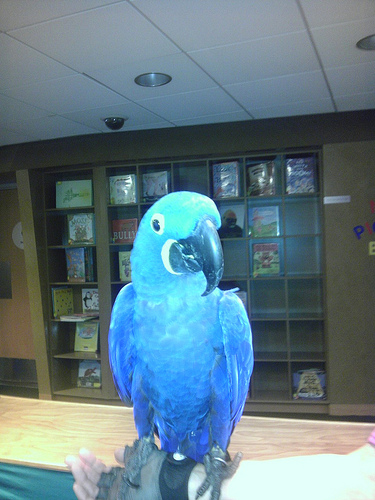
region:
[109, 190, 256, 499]
Large blue parrot on a man's arm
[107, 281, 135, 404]
Parrot's feathery blue right wing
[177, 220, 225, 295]
Parrot's curled pointy black beak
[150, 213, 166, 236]
Parrot's black and white right eye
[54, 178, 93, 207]
Book displayed in a cubby hole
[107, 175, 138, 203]
Book displayed in a cubby hole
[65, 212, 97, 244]
Book displayed in a cubby hole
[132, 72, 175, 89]
Round light in the middle of a white ceiling tile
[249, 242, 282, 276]
Book displayed in a cubby hole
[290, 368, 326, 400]
Book displayed in a cubby hole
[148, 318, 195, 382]
the bird's belly feathers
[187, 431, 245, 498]
the bird's left foot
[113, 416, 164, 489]
the bird's right foot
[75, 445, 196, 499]
a grey hand glove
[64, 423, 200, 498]
a man's gloved hand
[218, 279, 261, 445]
the bird's left wing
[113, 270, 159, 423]
the bird's white wing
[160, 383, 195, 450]
the bird's lower belly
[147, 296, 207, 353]
the bird's blue chest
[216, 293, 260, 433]
very blue wing feathers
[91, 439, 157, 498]
Glove on a person's right hand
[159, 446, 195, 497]
Black snapped wrist band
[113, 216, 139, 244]
Red BULLY book on a shelf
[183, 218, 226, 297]
Parrot's beak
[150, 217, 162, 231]
Parrot's right eye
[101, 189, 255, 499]
Blue parrot on a man's right hand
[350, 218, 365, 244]
Blue letter P on a shelf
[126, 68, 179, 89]
Inset light on a ceiling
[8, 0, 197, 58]
White tile on a ceiling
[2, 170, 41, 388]
Brown door with metal handle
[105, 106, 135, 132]
camera on the ceiling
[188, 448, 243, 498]
paw of a parrot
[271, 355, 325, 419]
book on a shelf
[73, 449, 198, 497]
glove for holding a bird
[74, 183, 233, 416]
Blue parrot with feathers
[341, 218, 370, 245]
the letters p and i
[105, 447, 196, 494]
silver buckle on glove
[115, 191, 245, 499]
bird perched on an arm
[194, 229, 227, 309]
black beak of a bird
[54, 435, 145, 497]
fingers in a glove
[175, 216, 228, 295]
the black beak of a bird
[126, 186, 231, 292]
the head of a bird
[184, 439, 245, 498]
the talon of a bird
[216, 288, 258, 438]
the wing of a bird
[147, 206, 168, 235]
the eye of a bird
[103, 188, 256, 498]
a large blue bird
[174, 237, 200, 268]
the mouth of the bird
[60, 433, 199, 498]
the hand of a person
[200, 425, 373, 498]
the arm of a person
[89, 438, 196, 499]
a gray glove without fingers